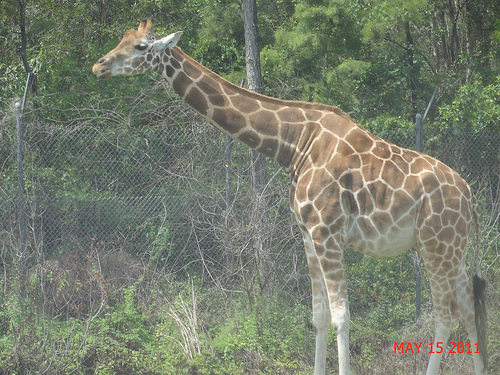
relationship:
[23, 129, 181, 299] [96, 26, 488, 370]
fence on giraffe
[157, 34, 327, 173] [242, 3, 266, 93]
big tree trunk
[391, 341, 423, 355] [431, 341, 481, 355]
letters and numbers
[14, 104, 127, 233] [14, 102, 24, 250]
metal fence post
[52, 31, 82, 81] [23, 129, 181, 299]
green behind fence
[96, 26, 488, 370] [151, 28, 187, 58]
giraffe has ears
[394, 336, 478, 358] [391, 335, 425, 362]
red text may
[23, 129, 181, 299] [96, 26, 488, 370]
fence behind giraffe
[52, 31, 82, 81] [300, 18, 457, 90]
green in trees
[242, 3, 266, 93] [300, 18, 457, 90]
trunk of trees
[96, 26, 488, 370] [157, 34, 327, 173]
giraffe has big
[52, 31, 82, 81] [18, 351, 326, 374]
green plants ground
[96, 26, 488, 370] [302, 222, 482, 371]
giraffe has legs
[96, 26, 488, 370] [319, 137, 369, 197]
giraffe has spots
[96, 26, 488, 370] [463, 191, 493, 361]
giraffe has tail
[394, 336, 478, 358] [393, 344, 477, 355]
date in red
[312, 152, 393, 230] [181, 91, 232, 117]
pattern on fure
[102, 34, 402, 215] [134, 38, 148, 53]
big black eyes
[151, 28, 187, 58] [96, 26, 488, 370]
ears on giraffe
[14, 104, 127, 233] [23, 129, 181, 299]
metal tall fence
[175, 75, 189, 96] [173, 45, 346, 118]
brown short mane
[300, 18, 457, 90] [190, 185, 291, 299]
trees and brush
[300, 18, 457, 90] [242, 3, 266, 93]
trees thin trunk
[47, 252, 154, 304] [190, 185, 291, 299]
dead brown brush